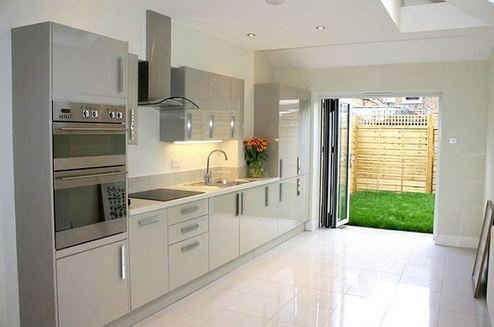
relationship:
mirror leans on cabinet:
[471, 200, 492, 294] [488, 229, 492, 306]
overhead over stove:
[139, 96, 193, 112] [136, 186, 206, 204]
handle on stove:
[53, 169, 131, 181] [49, 161, 127, 249]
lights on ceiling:
[246, 24, 341, 74] [1, 2, 493, 71]